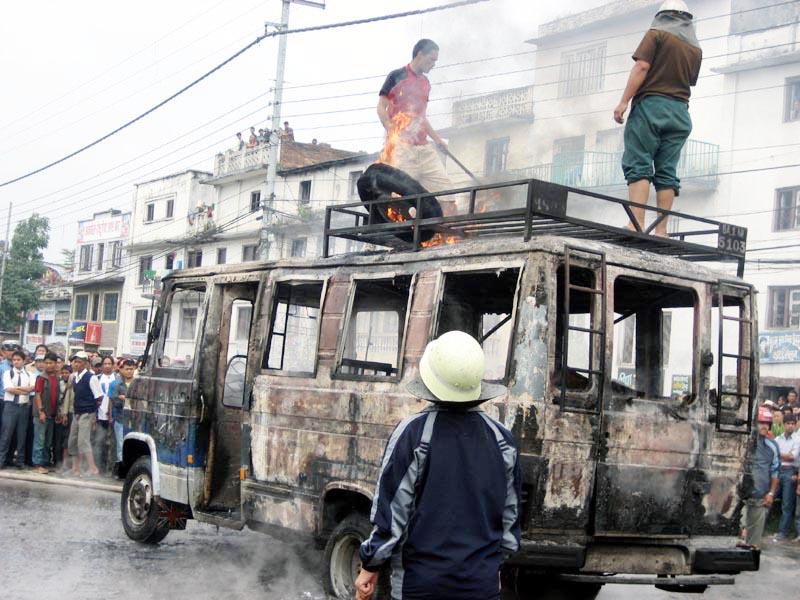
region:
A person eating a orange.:
[248, 362, 358, 448]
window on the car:
[608, 285, 677, 397]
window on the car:
[561, 275, 605, 399]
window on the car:
[699, 311, 739, 412]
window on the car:
[330, 287, 392, 370]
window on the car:
[277, 304, 305, 368]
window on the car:
[137, 304, 199, 365]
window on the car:
[657, 311, 692, 361]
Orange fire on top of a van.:
[373, 110, 496, 252]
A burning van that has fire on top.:
[118, 177, 762, 598]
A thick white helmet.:
[420, 331, 486, 405]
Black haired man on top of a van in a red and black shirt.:
[376, 38, 459, 217]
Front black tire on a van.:
[118, 452, 172, 545]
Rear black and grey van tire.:
[320, 515, 386, 598]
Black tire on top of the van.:
[360, 164, 444, 244]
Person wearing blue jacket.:
[373, 413, 549, 570]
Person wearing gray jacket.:
[744, 437, 779, 483]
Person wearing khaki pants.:
[733, 497, 784, 570]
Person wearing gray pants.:
[5, 407, 35, 457]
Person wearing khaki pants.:
[63, 416, 100, 461]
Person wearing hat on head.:
[66, 351, 88, 370]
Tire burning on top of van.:
[370, 144, 447, 238]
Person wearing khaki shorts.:
[390, 149, 458, 202]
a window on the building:
[778, 182, 792, 199]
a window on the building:
[783, 75, 799, 119]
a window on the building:
[509, 137, 560, 215]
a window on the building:
[542, 118, 576, 210]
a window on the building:
[302, 179, 332, 220]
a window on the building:
[169, 199, 179, 231]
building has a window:
[774, 187, 798, 229]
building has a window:
[789, 80, 798, 107]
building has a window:
[767, 286, 797, 327]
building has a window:
[488, 143, 509, 186]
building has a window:
[299, 181, 313, 208]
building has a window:
[165, 198, 173, 214]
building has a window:
[146, 204, 155, 222]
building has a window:
[139, 255, 152, 287]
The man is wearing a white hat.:
[412, 332, 490, 406]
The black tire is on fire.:
[356, 95, 490, 245]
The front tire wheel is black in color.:
[117, 459, 168, 543]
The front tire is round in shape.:
[114, 459, 170, 547]